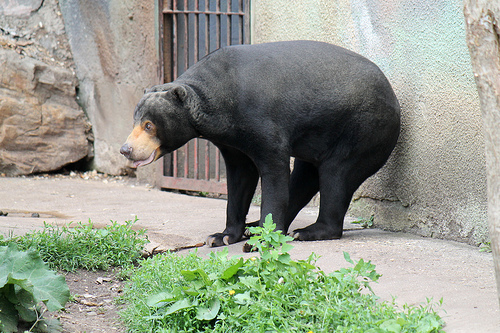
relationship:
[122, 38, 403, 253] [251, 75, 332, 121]
bear has a body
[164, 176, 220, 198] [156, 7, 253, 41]
bottom of door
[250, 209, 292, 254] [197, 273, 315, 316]
leaves on bush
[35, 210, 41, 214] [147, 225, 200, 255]
edge of rock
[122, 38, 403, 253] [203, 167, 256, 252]
bear has leg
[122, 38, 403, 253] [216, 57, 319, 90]
bear has a back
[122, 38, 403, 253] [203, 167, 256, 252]
bear has a leg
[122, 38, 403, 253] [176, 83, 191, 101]
bear has ear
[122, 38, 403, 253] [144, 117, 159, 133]
bear has left eye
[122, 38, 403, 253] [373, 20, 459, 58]
bear near wall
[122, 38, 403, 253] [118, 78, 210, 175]
bear has a head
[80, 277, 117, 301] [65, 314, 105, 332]
patch of dirt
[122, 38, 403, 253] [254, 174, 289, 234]
bear has left leg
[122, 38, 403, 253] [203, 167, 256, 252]
bear has right leg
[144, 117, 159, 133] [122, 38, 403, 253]
left eye of bear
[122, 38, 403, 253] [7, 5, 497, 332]
bear in zoo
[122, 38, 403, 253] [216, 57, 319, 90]
bear scratching h back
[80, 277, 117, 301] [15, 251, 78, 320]
patch of weeds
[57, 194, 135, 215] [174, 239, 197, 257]
sidewalk has a crack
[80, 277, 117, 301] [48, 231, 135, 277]
patch of grass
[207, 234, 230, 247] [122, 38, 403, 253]
claws of bear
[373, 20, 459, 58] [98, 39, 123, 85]
wall has red swirl